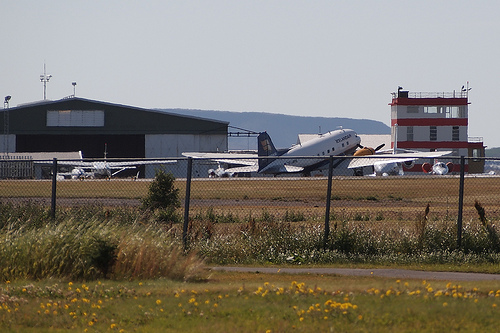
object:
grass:
[0, 220, 495, 332]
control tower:
[388, 81, 487, 175]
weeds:
[197, 205, 417, 220]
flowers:
[235, 272, 332, 301]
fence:
[0, 156, 500, 251]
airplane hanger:
[0, 96, 229, 180]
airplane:
[181, 126, 453, 178]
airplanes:
[51, 150, 177, 180]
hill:
[150, 108, 391, 148]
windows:
[407, 127, 413, 133]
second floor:
[390, 126, 468, 142]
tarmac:
[14, 172, 493, 182]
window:
[342, 143, 345, 147]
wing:
[347, 150, 453, 168]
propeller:
[353, 143, 386, 156]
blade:
[374, 144, 385, 152]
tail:
[181, 131, 304, 176]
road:
[201, 266, 499, 281]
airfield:
[4, 80, 499, 208]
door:
[142, 134, 202, 178]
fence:
[390, 91, 468, 99]